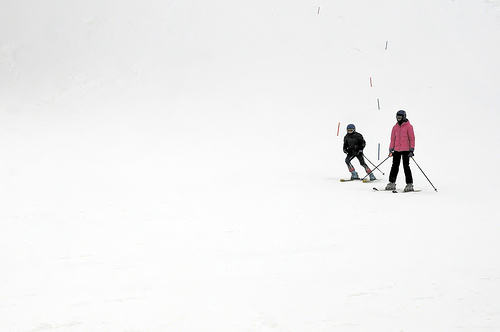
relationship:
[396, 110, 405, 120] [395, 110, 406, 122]
skully on a head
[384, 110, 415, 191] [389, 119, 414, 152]
kid wearing a jacket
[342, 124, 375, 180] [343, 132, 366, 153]
person wearing a jacket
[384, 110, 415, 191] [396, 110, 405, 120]
kid wearing a hat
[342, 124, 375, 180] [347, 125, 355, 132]
person wearing a skully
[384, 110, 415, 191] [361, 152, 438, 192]
kid holding ski poles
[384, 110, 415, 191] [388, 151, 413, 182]
kid wearing pants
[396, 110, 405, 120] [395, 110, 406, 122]
skully on head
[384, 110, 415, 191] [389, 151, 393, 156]
kid has a glove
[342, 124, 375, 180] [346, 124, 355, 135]
person has a head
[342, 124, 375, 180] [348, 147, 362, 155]
person has a torso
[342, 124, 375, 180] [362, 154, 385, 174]
person has a pole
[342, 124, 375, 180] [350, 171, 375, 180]
person has shoes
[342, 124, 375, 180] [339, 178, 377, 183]
person has skis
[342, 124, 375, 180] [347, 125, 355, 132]
person has a skully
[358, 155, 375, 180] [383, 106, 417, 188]
left leg of kid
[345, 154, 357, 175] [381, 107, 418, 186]
right leg of kid